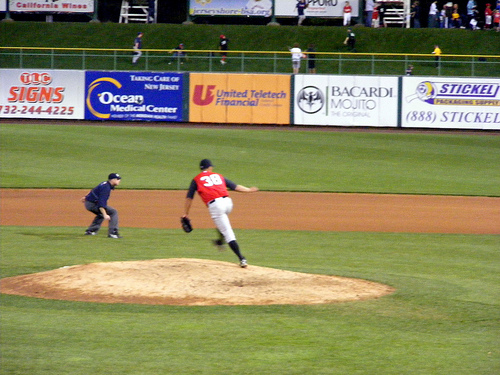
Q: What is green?
A: The grass.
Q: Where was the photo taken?
A: At a baseball game.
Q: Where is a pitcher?
A: On the pitcher's mound.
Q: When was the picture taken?
A: Daytime.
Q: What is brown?
A: Dirt.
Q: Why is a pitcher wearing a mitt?
A: He is playing baseball.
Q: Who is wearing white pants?
A: The pitcher.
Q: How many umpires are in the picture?
A: One.